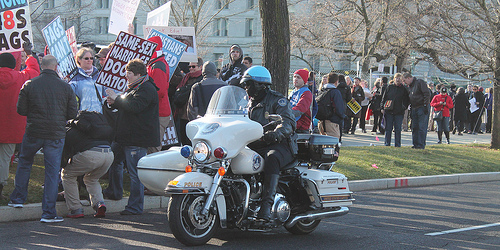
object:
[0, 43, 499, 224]
people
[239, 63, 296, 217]
policeman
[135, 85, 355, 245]
motorcycle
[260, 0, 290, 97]
tree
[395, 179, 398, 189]
line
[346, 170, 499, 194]
curb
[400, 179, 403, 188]
line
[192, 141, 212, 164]
headlight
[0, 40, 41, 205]
person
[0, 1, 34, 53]
sign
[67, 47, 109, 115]
person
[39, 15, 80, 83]
sign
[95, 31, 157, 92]
sign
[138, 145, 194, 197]
sidecar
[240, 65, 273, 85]
helmet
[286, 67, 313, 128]
person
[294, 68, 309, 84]
hat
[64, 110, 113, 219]
man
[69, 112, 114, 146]
backpack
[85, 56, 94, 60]
sunglasses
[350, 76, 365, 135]
man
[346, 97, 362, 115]
sign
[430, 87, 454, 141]
woman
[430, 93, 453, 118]
coat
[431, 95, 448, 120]
purse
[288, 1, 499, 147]
tree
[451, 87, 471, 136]
person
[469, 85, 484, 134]
person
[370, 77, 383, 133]
person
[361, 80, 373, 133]
person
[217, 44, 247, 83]
man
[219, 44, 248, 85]
hoodie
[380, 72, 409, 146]
person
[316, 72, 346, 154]
person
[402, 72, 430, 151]
person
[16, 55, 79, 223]
person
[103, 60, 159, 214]
person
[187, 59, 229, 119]
person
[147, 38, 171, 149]
person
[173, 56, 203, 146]
person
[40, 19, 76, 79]
writing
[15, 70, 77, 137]
coat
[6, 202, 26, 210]
foot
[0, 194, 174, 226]
curb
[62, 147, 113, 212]
pants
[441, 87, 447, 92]
hat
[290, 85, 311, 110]
scarf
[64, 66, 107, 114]
jacket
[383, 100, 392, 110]
bag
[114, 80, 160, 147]
jacket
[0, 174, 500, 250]
road